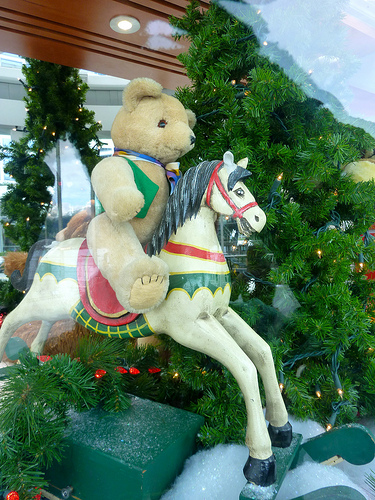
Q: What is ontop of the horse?
A: A teddy bear.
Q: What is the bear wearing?
A: A vest.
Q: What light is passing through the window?
A: Sunlight.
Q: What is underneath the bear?
A: A horse.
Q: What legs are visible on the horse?
A: The front legs.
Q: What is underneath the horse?
A: A green box.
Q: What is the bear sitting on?
A: A rocking horse.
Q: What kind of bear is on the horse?
A: A teddy bear.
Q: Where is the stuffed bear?
A: Riding the white horse.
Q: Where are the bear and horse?
A: In front of green decorations.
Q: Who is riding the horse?
A: A stuffed bear.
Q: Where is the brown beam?
A: Over the bear's head.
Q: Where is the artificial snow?
A: Under the horse.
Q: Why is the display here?
A: For the holidays.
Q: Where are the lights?
A: On the artificial tree.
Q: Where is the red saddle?
A: On the horse.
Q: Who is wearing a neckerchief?
A: The bear.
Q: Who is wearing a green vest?
A: The bear.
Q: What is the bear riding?
A: A horse.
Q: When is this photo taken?
A: During holidays.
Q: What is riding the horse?
A: A bear.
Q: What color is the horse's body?
A: White.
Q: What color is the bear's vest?
A: Green.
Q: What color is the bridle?
A: Red.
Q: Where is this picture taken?
A: At a mall.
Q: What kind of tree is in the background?
A: Christmas tree.